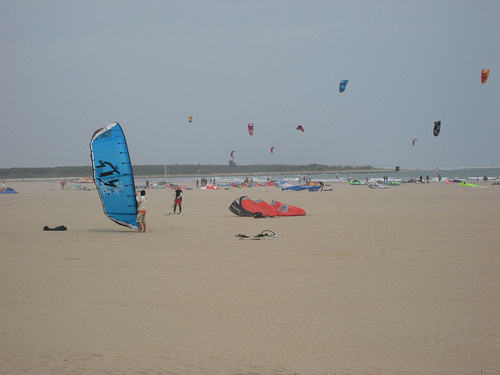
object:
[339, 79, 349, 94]
kite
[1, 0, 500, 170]
sky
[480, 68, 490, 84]
kite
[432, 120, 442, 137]
kite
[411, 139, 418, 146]
kite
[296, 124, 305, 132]
kite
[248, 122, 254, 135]
kite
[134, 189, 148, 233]
person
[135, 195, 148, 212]
shirt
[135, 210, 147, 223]
shorts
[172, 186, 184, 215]
person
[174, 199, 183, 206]
shorts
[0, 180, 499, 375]
beach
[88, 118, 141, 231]
kite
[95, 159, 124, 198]
design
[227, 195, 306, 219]
kite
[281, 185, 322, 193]
kite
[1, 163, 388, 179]
vegetation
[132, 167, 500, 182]
bay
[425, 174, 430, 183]
person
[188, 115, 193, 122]
kite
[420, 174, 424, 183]
person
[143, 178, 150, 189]
person